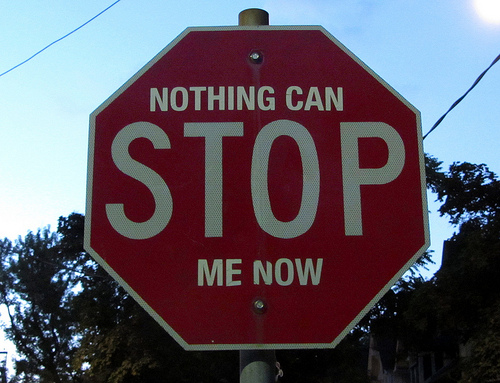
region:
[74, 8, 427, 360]
red sign with white lettering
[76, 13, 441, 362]
red sign with white edges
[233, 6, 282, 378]
pole sign is affixed to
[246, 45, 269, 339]
silver bolts holding sign to pole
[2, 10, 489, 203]
two black power lines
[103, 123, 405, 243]
white lettering on red background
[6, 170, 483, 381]
tree tops behind stop sign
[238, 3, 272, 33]
top of pole stop sign is on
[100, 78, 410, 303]
nothing can stop me now in white on sign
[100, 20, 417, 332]
red background of stop sign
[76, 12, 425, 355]
red sign with white trim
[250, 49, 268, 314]
two silver bolts on sign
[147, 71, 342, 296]
white lettering added to sign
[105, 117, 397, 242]
white letters on red background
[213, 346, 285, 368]
shadow on bottom of pole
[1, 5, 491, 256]
two power lines behind stop sign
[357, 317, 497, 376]
roof of house on right side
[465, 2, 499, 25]
sun in the blue sky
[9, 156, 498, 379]
tree branches behind traffic sign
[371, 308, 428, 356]
black roof of house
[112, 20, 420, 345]
red and white sign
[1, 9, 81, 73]
white clouds in blue sky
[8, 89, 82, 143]
white clouds in blue sky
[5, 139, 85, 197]
white clouds in blue sky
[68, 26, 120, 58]
white clouds in blue sky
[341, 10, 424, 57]
white clouds in blue sky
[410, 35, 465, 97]
white clouds in blue sky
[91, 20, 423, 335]
red and white sign with graffiti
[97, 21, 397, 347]
red and white stop sign with graffiti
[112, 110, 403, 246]
white and red sign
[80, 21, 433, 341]
A red stop sign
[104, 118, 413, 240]
The word stop in white letters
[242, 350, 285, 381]
A silver metal pole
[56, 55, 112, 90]
Crystal clear blue skies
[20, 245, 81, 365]
Green tree branches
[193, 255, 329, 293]
Word's "me now" in white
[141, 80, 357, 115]
The words "nothing can" in white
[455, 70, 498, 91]
Cable wires against the blue sky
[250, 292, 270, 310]
A small silver screw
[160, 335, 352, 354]
A White border on sign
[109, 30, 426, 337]
Stop sign on a pole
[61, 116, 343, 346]
Stop sign on a pole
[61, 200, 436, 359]
Stop sign on a pole